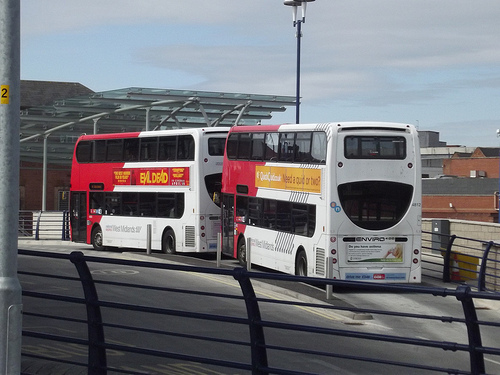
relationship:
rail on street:
[21, 246, 499, 373] [15, 238, 498, 371]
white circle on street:
[82, 262, 144, 284] [15, 238, 498, 371]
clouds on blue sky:
[318, 12, 495, 99] [18, 0, 498, 148]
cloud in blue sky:
[2, 0, 468, 46] [18, 0, 498, 148]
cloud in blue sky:
[144, 36, 498, 109] [18, 0, 498, 148]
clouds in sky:
[123, 32, 498, 89] [22, 0, 498, 87]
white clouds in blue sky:
[161, 29, 472, 107] [18, 0, 498, 148]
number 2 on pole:
[2, 85, 8, 102] [0, 1, 24, 373]